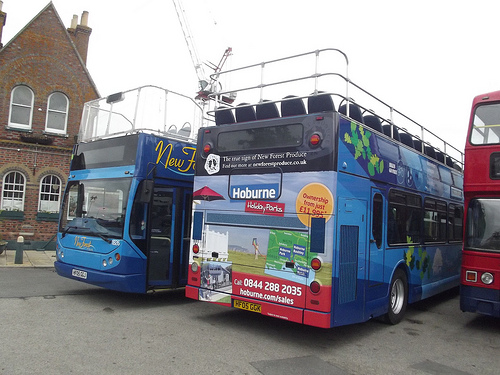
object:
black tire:
[378, 268, 408, 325]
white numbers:
[244, 277, 302, 296]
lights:
[309, 257, 323, 294]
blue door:
[366, 187, 387, 301]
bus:
[186, 47, 465, 332]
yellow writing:
[154, 140, 195, 172]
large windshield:
[59, 177, 132, 237]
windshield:
[75, 84, 202, 141]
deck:
[68, 128, 198, 170]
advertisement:
[195, 149, 334, 176]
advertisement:
[184, 170, 337, 327]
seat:
[215, 106, 234, 124]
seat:
[256, 99, 280, 119]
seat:
[308, 90, 336, 113]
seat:
[363, 115, 383, 133]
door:
[146, 184, 184, 290]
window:
[387, 190, 464, 245]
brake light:
[204, 116, 324, 152]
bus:
[53, 84, 202, 295]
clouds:
[98, 0, 500, 56]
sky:
[1, 1, 497, 116]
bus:
[459, 90, 499, 318]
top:
[193, 47, 466, 202]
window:
[7, 85, 35, 130]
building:
[0, 0, 100, 249]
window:
[45, 91, 69, 133]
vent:
[337, 226, 360, 305]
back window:
[216, 123, 303, 153]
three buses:
[53, 47, 500, 331]